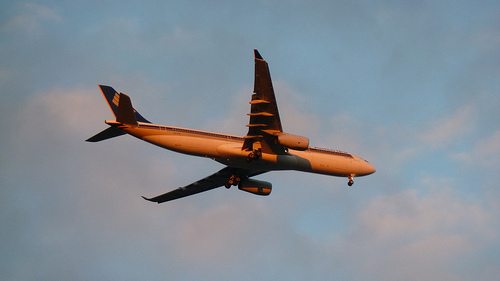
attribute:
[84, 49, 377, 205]
airplane — big, white, long, alone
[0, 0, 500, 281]
sky — blue, cloudy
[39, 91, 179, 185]
cloud — white, wispy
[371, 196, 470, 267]
cloud — white, wispy